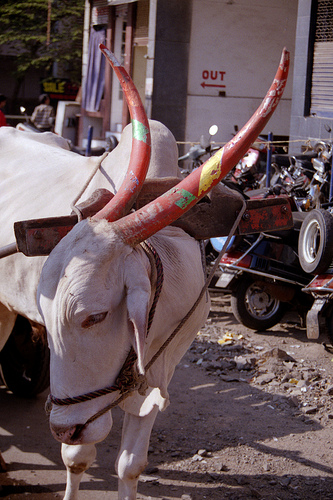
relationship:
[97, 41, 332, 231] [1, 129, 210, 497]
horns on goat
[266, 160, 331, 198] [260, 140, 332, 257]
junk in a pile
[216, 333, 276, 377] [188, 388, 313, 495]
garbage on street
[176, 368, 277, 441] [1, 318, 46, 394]
shadow of cart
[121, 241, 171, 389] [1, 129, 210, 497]
rope around goat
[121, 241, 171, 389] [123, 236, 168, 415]
rope around neck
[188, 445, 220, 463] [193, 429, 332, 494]
rocks on top of ground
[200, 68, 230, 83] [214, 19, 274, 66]
writing on wall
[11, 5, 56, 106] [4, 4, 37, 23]
tree has leaves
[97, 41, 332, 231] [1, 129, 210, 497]
horns are on goat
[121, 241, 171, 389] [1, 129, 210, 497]
rope on goat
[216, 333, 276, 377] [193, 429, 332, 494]
garbage on top of ground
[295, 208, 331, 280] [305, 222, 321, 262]
tire has rim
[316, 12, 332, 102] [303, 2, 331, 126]
curtain in window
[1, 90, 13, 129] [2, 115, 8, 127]
person has shirt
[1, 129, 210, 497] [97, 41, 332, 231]
goat has horns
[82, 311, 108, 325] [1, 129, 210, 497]
eye of goat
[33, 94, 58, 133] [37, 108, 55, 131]
man wearing shirt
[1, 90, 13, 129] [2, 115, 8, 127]
person in shirt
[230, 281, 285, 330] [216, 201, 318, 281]
tire on rear of motorcycle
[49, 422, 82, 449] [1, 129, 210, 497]
nose on goat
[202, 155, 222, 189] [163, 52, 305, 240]
paint on horn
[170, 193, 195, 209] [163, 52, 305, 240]
paint on horn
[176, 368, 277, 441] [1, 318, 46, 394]
shadow made by cart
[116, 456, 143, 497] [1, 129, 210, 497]
knee of goat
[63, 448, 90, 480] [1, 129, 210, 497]
knee of goat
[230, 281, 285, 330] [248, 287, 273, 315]
tire has rim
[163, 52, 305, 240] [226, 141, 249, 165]
horn painted red